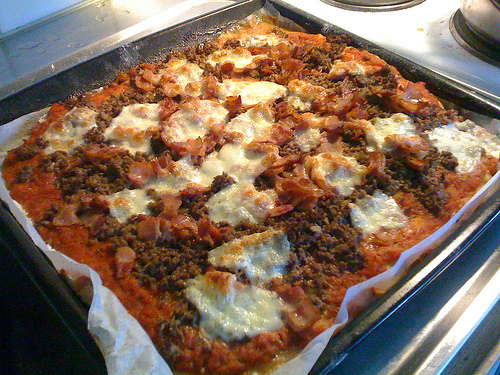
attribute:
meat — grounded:
[67, 112, 467, 362]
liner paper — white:
[84, 283, 175, 372]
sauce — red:
[3, 8, 499, 373]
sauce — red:
[3, 153, 227, 373]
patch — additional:
[86, 3, 133, 22]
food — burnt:
[4, 15, 498, 373]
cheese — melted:
[0, 17, 498, 372]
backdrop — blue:
[0, 2, 76, 35]